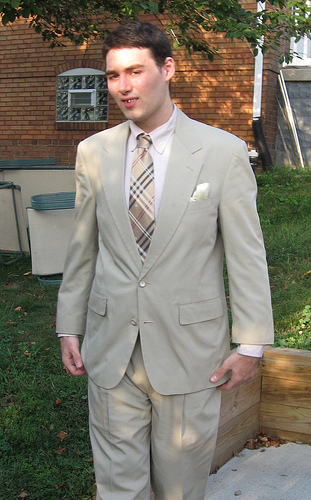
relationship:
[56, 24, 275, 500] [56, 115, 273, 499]
man in a suit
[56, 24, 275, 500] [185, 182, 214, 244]
man has a pocket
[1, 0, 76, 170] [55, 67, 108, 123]
house has a window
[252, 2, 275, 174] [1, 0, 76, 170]
gutters on building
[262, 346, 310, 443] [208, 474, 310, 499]
wood next to cement slab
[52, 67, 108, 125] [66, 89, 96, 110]
window has an airconditioner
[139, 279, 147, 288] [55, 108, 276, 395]
buttons on jacket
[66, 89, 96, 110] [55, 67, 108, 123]
ac unit in window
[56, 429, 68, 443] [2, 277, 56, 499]
leaves are on ground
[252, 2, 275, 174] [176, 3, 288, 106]
rain gutters on wall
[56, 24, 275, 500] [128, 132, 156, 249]
man with a tie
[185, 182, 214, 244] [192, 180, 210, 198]
pocket has a handkerchief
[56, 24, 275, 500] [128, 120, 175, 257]
boy wearing shirt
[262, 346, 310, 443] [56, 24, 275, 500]
wall next to man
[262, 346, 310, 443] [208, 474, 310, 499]
wood framing for slab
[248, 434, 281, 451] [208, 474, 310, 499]
leaves on cement slab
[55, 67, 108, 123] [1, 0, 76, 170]
window on building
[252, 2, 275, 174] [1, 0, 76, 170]
rain gutters on building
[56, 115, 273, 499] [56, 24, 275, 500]
blazer on man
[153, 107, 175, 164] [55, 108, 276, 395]
dress shirt under jacket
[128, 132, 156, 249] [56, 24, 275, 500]
tie on man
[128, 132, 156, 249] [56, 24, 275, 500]
tie worn by man